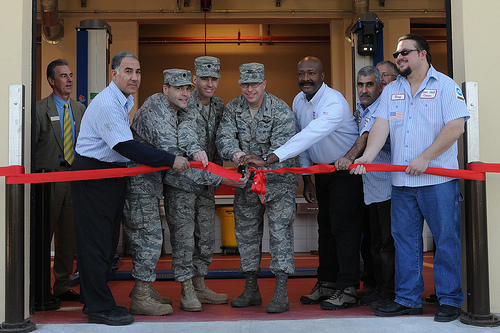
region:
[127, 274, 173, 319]
Army boots of the soldier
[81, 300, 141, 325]
Dress shoes of the person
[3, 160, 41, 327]
Post that holds the ribbon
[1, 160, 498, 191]
Red ribbon for opening of store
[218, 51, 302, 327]
Army man that is cutting ribbon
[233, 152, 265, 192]
Scissors being used to cut the ribbon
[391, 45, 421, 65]
Cool looking shades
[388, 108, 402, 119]
American flag on the guy's shirt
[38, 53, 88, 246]
Business guy that owns the store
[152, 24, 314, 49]
Pipe that is connected to plumbing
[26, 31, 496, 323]
men behind red ribbon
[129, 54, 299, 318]
three men in military uniform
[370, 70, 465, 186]
shirt with patches on front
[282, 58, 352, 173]
man in white shirt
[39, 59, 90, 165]
man in yellow tie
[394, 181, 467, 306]
blue jeans on legs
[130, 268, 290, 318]
boots on six feet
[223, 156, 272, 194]
hands cutting red ribbon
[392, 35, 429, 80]
man with sunglasses on face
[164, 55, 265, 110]
hats on three heads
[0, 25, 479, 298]
men are holding a ribbon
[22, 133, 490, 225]
the ribbon is red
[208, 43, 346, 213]
the two men are cutting the ribbon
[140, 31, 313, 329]
3 men are wearing uniforms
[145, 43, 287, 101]
the soldiers are wearing hats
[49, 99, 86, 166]
the tie is yellow and blue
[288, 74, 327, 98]
the man has a mustache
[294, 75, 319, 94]
the mustache is black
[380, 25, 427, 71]
man is wearing sunglasses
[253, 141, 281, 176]
man is wearing a bracelet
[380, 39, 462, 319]
the man has glasses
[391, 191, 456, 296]
jeans are blue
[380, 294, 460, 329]
shoes are black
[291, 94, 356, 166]
the shirt is white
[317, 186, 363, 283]
the pants are black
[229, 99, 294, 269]
the uniform is comouflauge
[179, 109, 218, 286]
the uniform is comouflouge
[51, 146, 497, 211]
the rope is red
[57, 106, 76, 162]
the tie is yellow and green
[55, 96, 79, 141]
the shirt s blue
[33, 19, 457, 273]
a group of employees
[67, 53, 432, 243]
these men are cutting a ribbon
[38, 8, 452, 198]
a ribbon cutting ceremony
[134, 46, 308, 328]
these men are in the military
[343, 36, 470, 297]
these guys are blue collar workers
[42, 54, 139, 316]
these guys are civilians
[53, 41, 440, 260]
they are enjoying this ribbon cutting ceremony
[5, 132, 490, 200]
they are cutting a red ribbon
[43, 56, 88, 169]
he is wearing a yellow tie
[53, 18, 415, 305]
they are at an entry point to cut the ribbon